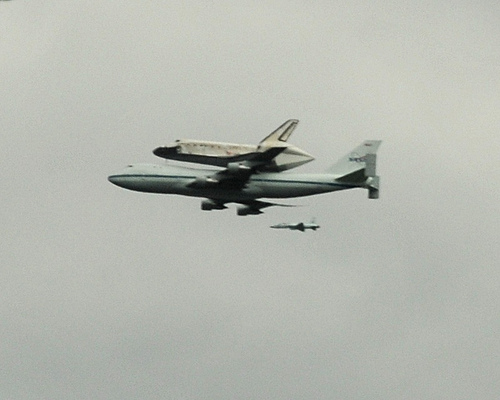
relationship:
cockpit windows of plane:
[126, 163, 135, 171] [99, 140, 383, 231]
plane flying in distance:
[269, 220, 321, 233] [1, 2, 482, 397]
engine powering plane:
[225, 158, 259, 172] [105, 137, 383, 216]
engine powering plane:
[192, 172, 224, 187] [105, 137, 383, 216]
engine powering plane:
[197, 193, 229, 211] [105, 137, 383, 216]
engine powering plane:
[232, 203, 263, 215] [105, 137, 383, 216]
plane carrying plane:
[105, 137, 383, 216] [151, 115, 315, 174]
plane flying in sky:
[105, 137, 383, 216] [1, 1, 484, 395]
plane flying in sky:
[269, 214, 321, 232] [1, 1, 484, 395]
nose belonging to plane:
[105, 170, 120, 184] [105, 137, 383, 216]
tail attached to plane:
[322, 137, 383, 197] [105, 137, 383, 216]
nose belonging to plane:
[152, 144, 180, 159] [151, 115, 315, 174]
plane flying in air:
[105, 137, 383, 216] [1, 1, 483, 396]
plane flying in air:
[269, 220, 321, 233] [1, 1, 483, 396]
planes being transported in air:
[150, 119, 319, 173] [1, 1, 483, 396]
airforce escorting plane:
[265, 222, 319, 236] [105, 137, 383, 216]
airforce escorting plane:
[265, 222, 319, 236] [151, 115, 315, 174]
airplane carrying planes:
[107, 137, 384, 217] [150, 119, 319, 173]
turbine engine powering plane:
[200, 196, 230, 212] [105, 137, 383, 216]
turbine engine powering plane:
[236, 201, 264, 216] [105, 137, 383, 216]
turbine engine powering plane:
[222, 156, 258, 174] [105, 137, 383, 216]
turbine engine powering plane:
[191, 173, 222, 186] [105, 137, 383, 216]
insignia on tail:
[347, 148, 368, 167] [336, 124, 388, 194]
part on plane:
[266, 116, 292, 144] [167, 110, 310, 171]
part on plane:
[335, 146, 399, 204] [135, 147, 384, 197]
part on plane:
[277, 142, 306, 171] [131, 111, 320, 175]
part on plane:
[277, 142, 306, 171] [145, 96, 311, 171]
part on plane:
[106, 165, 205, 201] [87, 152, 395, 211]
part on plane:
[260, 170, 341, 202] [101, 154, 372, 198]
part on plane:
[266, 222, 316, 235] [259, 211, 325, 236]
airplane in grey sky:
[107, 139, 383, 218] [53, 233, 465, 375]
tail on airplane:
[322, 137, 383, 197] [107, 137, 384, 217]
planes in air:
[88, 103, 398, 251] [1, 1, 483, 396]